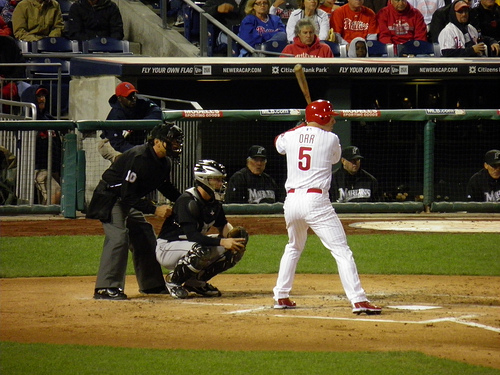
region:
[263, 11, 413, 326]
baseball player swinging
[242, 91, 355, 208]
Jersey with Orr and number 5 on the back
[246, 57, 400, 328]
red helmet and shoes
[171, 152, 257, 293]
catcher awaiting pitch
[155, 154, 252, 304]
catcher wearing protective mask and helmet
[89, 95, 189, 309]
umpire awaiting pitch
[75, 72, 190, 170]
player in dugout wearing red hat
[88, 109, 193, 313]
number 10 on umpire's sleve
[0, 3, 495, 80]
fans watching baseball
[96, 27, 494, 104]
ads on roof of dugout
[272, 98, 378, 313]
baseball player with red and white uniform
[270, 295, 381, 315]
red and gray shoes of baseball player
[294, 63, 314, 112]
brown wooden baseball bat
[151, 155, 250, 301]
catcher in black and gray uniform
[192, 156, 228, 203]
black and gray helmet of catcher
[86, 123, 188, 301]
umpier with black and gray uniform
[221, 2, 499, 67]
bunch of people sitting on terraces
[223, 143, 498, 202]
baseball players with black uniforms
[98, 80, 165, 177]
man standing with red cap and blue sweater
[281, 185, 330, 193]
red belt of batsman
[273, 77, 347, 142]
man's helmet is red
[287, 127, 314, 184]
red number on shirt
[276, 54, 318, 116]
man holding a bat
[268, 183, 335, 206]
man's belt is red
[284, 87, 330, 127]
light shining on helmet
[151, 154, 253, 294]
man is squatting down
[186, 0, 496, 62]
fans watching the game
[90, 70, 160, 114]
man is wearing a hat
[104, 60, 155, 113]
man's hat is red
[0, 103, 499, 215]
the railing is green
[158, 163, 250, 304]
A catcher.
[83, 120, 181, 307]
An umpire.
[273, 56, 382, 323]
A batter.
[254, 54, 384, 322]
A man about to swing a baseball bat.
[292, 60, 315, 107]
A brown baseball bat.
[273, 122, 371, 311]
A red and white uniform.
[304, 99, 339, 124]
A red baseball helmet.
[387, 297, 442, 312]
A white home plate.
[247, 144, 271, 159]
A black and white ball cap.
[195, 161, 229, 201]
A silver helmet with face protector.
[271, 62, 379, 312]
a batter getting ready to hit the ball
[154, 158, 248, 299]
a catcher waiting for the ball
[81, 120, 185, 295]
an umpire waiting for the pitch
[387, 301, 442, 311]
home plate next to the batter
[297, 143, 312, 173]
red number on the back of the player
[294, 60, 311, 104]
bat held by the baseball player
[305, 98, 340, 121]
red helmet on the batter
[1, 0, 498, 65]
audience watching the game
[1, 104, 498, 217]
green fence behind the players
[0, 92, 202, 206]
metal fence behind the green fence